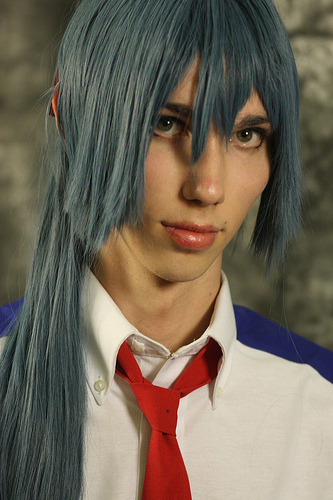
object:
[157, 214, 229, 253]
lips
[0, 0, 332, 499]
guy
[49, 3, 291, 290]
head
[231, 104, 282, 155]
eye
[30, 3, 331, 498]
person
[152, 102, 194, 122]
eyeliner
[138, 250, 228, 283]
chin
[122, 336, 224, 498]
neck tie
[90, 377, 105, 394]
button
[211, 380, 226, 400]
button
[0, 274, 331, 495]
shirt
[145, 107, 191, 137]
eye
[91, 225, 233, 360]
neck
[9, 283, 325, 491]
costume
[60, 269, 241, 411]
collar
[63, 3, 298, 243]
hair